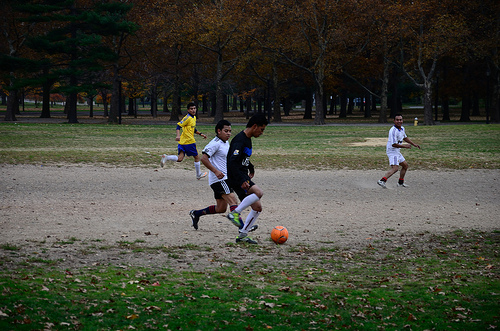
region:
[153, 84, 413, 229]
men playing soccer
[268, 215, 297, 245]
the soccer ball on the sand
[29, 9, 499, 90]
trees with brown leaves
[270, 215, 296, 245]
the ball is orange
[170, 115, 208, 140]
man wearing yellow shirt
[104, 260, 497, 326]
leaves in the grass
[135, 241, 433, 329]
leaves are brown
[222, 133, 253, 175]
man wearing black shirt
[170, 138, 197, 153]
man wearing blue shorts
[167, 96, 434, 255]
the men are running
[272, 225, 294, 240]
BALL IS IN THE FIELD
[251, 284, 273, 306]
BROWN LEAVES OVER THE GRASS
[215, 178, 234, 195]
WHITE STRIPES ON THE SIDE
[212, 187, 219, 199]
BOY IS WEARING BLACK SHORTS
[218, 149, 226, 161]
BOY HAS ON A GREY SHIRT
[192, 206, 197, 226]
BOY WEARING BLACK SHOES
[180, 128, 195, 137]
BOY HAS ON A YELLOW SHIRT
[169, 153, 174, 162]
BOY HAS ON WHITE SOCKS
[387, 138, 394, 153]
BOY HAS ON A WHITE SHIRT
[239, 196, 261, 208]
BOY IS WEARING LONG WHITE SOCKS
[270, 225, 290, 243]
Orange soccer ball on ground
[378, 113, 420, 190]
Man in white shirt and shorts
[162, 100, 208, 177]
Young man in yellow shirt and blue shorts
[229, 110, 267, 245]
Young man in black shirt and shorts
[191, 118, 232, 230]
Young man in white shirt and black shorts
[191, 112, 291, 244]
Two men going after soccer ball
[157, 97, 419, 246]
Four men playing soccer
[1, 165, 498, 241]
Brown sandy area on ground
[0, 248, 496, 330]
Brown leaves scattered on green grass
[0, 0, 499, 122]
Tall trees with multi-colored leaves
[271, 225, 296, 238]
the ball is red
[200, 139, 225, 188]
the shirt is white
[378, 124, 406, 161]
the clothes are white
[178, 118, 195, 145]
the shirt is yellow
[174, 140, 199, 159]
the shorts are blue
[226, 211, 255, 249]
the boots are green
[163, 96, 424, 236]
the people are playing soccer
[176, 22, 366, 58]
the leaves are brown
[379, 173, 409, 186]
the socks are red and black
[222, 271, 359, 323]
brown leaves are on the grass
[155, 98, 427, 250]
Men are playing soccer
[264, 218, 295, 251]
An orange soccer ball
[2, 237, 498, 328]
Leaves are on the grass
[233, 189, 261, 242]
A pair of long white socks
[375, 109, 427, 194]
Man wearing a white outfit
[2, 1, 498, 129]
Many trees are in the background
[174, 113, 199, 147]
A shirt is yellow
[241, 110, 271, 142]
A guy has black hair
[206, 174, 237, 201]
White stripes on black shorts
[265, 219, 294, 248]
Soccer ball is round